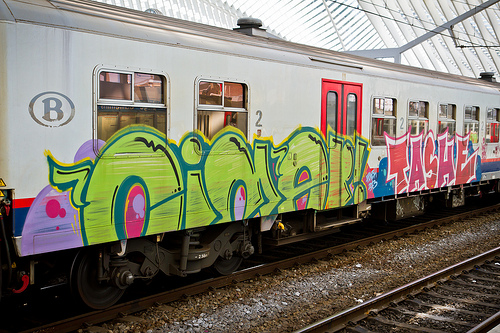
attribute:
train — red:
[2, 1, 497, 269]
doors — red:
[319, 81, 364, 230]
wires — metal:
[341, 2, 493, 78]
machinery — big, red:
[8, 259, 33, 314]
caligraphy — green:
[41, 118, 375, 248]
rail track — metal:
[293, 250, 492, 332]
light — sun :
[251, 2, 359, 43]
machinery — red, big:
[12, 268, 52, 312]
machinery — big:
[5, 261, 36, 302]